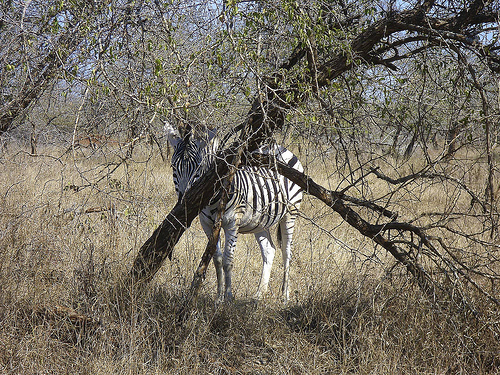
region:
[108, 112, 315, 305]
black and white striped zebra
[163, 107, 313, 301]
zebra standing behind tree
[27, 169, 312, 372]
dry brown brush growing on ground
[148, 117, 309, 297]
one striped white zebra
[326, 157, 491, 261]
bare branches growing from tree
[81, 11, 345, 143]
small green leaves on tree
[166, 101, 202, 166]
black mane on zebra's head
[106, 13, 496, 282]
bent over tree with branches extending to ground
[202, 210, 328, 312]
mostly white zebra legs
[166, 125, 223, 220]
black and white striped face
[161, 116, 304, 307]
a black and white zebra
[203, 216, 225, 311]
a black and white leg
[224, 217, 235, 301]
a black and white leg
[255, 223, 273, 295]
a black and white leg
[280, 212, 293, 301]
a black and white leg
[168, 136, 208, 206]
a black and white head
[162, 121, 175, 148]
a white ear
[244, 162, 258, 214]
the black stripe of a zebra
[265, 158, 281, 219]
the black stripe of a zebra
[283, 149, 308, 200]
the black stripe of a zebra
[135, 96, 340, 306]
black and white zebra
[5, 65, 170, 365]
dry yellow brush and grass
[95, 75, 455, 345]
zebra out in the wild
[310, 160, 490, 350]
dead tree branches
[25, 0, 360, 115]
green leaves on tree branches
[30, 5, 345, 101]
blue sky behind branches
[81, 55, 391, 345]
a tree trunk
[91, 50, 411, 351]
tree trunk blocking zebra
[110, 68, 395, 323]
zebra standing among dry grass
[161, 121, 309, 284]
zebra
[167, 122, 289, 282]
striped zebra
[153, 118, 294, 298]
black and white striped zebra on plain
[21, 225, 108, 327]
very tall brown and yellow grass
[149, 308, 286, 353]
very tall brown and yellow grass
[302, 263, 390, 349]
very tall brown and yellow grass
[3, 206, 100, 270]
very tall brown and yellow grass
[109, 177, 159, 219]
very tall brown and yellow grass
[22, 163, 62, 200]
very tall brown and yellow grass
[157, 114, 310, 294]
zebra in the grass.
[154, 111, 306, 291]
only one zebra is visible.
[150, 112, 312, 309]
zebra is black and white.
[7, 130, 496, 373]
the grass is dry.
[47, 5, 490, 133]
the sky is blue.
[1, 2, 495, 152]
sky shining through the trees.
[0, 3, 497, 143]
green leaves on the trees.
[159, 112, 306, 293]
the zebra is striped.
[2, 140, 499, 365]
the grass is brown.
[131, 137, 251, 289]
the tree trunk is brown.